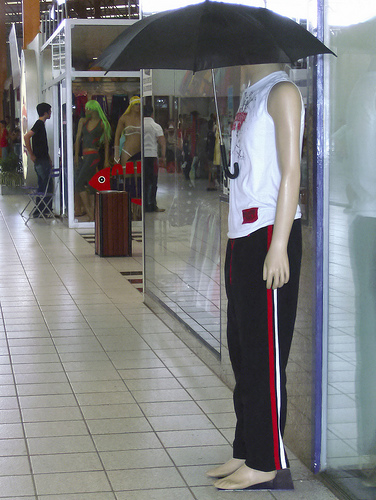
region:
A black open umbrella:
[94, 2, 337, 177]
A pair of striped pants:
[221, 213, 297, 465]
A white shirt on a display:
[221, 67, 292, 225]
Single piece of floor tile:
[71, 399, 139, 412]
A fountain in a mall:
[94, 188, 129, 253]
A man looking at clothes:
[18, 96, 53, 211]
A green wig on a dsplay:
[79, 94, 107, 137]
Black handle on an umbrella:
[213, 137, 237, 172]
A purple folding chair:
[18, 160, 54, 214]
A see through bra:
[121, 119, 141, 131]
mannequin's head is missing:
[217, 68, 302, 496]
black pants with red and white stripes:
[220, 223, 299, 470]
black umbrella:
[111, 15, 327, 180]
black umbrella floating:
[113, 23, 307, 169]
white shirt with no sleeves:
[229, 87, 314, 247]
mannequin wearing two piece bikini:
[116, 94, 143, 177]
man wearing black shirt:
[19, 91, 53, 166]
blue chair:
[30, 170, 63, 216]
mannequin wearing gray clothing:
[73, 98, 106, 209]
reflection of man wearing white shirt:
[142, 107, 171, 221]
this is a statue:
[169, 164, 324, 316]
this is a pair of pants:
[186, 292, 288, 378]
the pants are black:
[213, 318, 297, 414]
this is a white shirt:
[238, 152, 271, 186]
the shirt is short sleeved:
[204, 157, 303, 213]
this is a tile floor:
[109, 360, 143, 434]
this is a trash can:
[59, 192, 148, 252]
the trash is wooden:
[78, 187, 130, 245]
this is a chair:
[16, 182, 48, 211]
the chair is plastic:
[3, 184, 49, 208]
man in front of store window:
[29, 102, 64, 216]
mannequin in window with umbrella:
[98, 3, 319, 498]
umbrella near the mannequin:
[98, 2, 289, 196]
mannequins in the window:
[82, 96, 143, 225]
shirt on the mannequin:
[201, 74, 308, 228]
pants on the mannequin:
[235, 222, 305, 469]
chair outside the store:
[16, 169, 64, 220]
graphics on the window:
[88, 156, 157, 205]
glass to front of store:
[145, 73, 305, 318]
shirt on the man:
[15, 120, 53, 153]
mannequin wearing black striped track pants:
[212, 64, 304, 489]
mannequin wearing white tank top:
[210, 69, 305, 492]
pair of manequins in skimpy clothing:
[69, 92, 144, 206]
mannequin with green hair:
[69, 95, 113, 226]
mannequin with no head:
[124, 2, 315, 489]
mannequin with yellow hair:
[109, 88, 159, 171]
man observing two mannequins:
[19, 101, 71, 221]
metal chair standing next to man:
[25, 157, 57, 223]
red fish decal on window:
[85, 155, 141, 210]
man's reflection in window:
[145, 105, 169, 215]